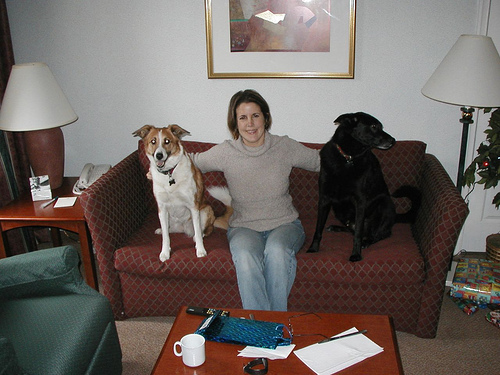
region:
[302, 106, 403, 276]
a black dog sitting on a couch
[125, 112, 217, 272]
a white and brown dog sitting on a couch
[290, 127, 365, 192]
an arm around a dog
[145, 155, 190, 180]
collar on a dog's neck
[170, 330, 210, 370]
coffee cup on a table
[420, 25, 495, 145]
a white lamp shade on a lamp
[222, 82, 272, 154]
woman with a big smile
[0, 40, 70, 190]
lamp on a table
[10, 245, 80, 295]
blue arm of a couch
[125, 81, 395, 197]
woman with her dogs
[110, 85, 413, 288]
A woman sitting with two dogs.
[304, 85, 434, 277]
a black dog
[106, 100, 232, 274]
A brown and white dog on a sofa.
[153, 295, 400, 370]
a brown coffee table in a living room.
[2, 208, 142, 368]
A green recliner beside a coffee table.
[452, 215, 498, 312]
Wrapped presents on the floor.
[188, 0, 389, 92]
One picture hanging on a wall.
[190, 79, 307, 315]
A woman in a tan sweater.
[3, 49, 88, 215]
A table lamp on an end table.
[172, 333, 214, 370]
coffee mug on a brown coffee table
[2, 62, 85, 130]
white lamp shade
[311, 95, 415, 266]
black dog with a brown collar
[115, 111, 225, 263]
white and brown dog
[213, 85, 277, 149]
a woman with brown hair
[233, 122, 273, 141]
a person smiling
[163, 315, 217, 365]
a white coffee mug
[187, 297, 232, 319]
black remote control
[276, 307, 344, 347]
eyeglasses on a table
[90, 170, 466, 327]
a maroon couch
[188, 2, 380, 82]
framed picture on a wall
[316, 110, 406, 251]
Black dog looking to the right.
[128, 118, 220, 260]
White and tan dog facing forward.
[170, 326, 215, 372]
White coffee mug on table.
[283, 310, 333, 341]
Eye glasses on center table.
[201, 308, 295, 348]
Blue gift bag on table.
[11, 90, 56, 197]
Small lamp on side table.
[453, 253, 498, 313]
Gift under tree to the right of the burgundy sofa.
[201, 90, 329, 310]
Woman sitting on sofa.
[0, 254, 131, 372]
Recliner on the left of center table.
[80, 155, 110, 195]
Telephone on side table.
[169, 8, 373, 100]
GOLD PICTURE FRAME MOUNTED ON WALL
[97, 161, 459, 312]
RED AND GOLD SOFA FOR SITTING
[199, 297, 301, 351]
EMPTY BLUE GIFT BAG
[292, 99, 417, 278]
BLACK DOG SITTING ON COUCH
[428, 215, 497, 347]
STACKED WRAPPED GIFTS ON FLOOR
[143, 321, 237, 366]
WHITE COFFEE CUP SITTING ON COFFEE TABLE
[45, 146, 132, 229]
WHITE TELEPHONE ON SIDE TABLE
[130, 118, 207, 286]
BROWN AND WHITE DOG SITTING ON SOFA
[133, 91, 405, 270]
SMILING YOUNG WOMAN SITTING ON COUCH WITH TWO DOGS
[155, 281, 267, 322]
TELEVISION REMOTE SITS ON COFFEE TABLE